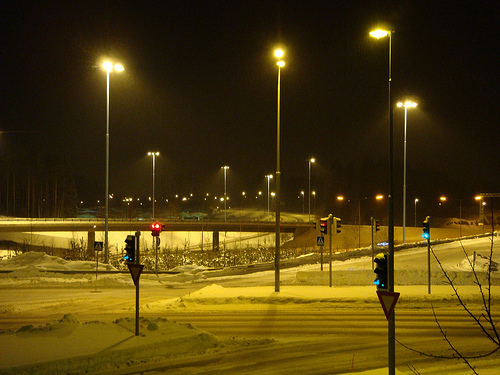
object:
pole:
[104, 72, 111, 264]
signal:
[373, 251, 396, 291]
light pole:
[274, 67, 282, 292]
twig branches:
[395, 209, 500, 375]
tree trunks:
[0, 161, 66, 218]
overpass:
[0, 216, 316, 259]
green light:
[422, 222, 430, 239]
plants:
[110, 249, 310, 270]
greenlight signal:
[373, 252, 387, 287]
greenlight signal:
[123, 235, 135, 262]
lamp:
[114, 63, 126, 73]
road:
[0, 236, 500, 375]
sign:
[93, 241, 103, 279]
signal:
[123, 234, 136, 265]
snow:
[0, 311, 227, 375]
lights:
[273, 47, 286, 68]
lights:
[369, 28, 390, 39]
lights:
[396, 99, 418, 108]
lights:
[147, 151, 160, 156]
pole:
[223, 169, 227, 222]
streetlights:
[145, 150, 273, 221]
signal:
[396, 99, 418, 109]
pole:
[155, 236, 159, 275]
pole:
[387, 30, 395, 291]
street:
[0, 216, 500, 375]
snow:
[155, 282, 496, 307]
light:
[150, 224, 154, 230]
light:
[154, 222, 162, 230]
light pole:
[152, 154, 155, 218]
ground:
[0, 223, 500, 375]